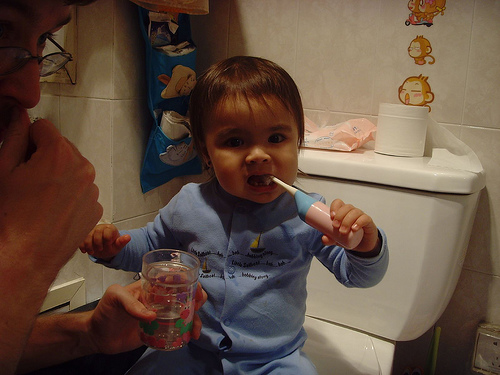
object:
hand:
[80, 215, 130, 254]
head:
[193, 51, 308, 200]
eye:
[218, 134, 247, 149]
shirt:
[115, 180, 388, 374]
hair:
[184, 54, 305, 157]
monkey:
[398, 33, 437, 103]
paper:
[366, 98, 489, 172]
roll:
[370, 97, 485, 182]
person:
[1, 1, 228, 372]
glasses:
[1, 42, 71, 78]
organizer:
[141, 16, 201, 196]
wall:
[0, 0, 499, 374]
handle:
[426, 322, 446, 372]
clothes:
[88, 175, 389, 372]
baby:
[77, 53, 390, 374]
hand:
[321, 197, 378, 255]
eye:
[267, 128, 290, 144]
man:
[0, 0, 206, 374]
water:
[145, 304, 201, 337]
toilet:
[0, 0, 499, 374]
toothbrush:
[260, 169, 373, 249]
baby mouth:
[240, 167, 280, 190]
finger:
[325, 204, 371, 237]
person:
[83, 59, 387, 373]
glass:
[137, 246, 198, 352]